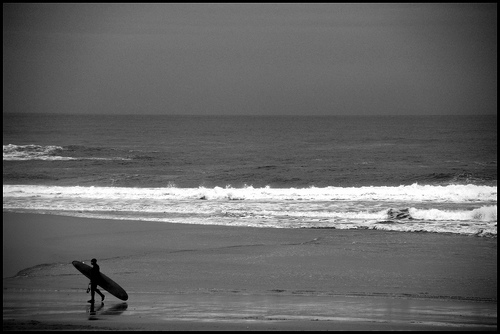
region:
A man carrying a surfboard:
[33, 239, 143, 324]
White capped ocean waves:
[1, 168, 498, 237]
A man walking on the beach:
[3, 58, 498, 333]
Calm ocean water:
[186, 118, 418, 153]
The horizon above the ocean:
[7, 15, 499, 154]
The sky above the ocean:
[11, 38, 496, 130]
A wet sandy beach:
[155, 230, 490, 314]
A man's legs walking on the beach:
[84, 283, 109, 311]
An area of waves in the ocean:
[0, 136, 135, 169]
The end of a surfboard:
[112, 283, 133, 303]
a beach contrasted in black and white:
[3, 112, 499, 329]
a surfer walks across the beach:
[71, 255, 130, 307]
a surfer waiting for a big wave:
[66, 257, 131, 311]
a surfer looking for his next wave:
[68, 256, 134, 308]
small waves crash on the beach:
[5, 183, 499, 237]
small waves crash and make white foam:
[5, 184, 499, 238]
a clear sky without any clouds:
[6, 0, 498, 113]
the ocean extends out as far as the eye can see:
[6, 114, 498, 235]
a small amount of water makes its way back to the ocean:
[4, 229, 499, 315]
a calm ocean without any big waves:
[5, 114, 499, 235]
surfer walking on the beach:
[57, 240, 132, 316]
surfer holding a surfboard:
[65, 243, 137, 318]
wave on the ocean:
[377, 200, 447, 234]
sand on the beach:
[291, 299, 419, 328]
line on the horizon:
[158, 101, 498, 132]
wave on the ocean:
[5, 133, 82, 173]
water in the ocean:
[341, 129, 450, 170]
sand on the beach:
[21, 221, 102, 246]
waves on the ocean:
[161, 171, 235, 207]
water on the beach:
[177, 296, 252, 327]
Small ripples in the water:
[8, 173, 53, 199]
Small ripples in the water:
[53, 171, 94, 200]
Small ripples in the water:
[95, 155, 127, 200]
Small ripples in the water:
[46, 132, 114, 164]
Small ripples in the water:
[10, 129, 39, 165]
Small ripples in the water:
[154, 175, 186, 197]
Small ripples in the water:
[182, 159, 260, 199]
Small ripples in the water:
[262, 168, 304, 205]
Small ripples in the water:
[303, 161, 368, 197]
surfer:
[54, 246, 133, 310]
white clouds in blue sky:
[385, 52, 438, 83]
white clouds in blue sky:
[331, 40, 382, 73]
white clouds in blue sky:
[226, 69, 268, 106]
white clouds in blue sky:
[89, 19, 174, 76]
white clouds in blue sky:
[137, 45, 173, 82]